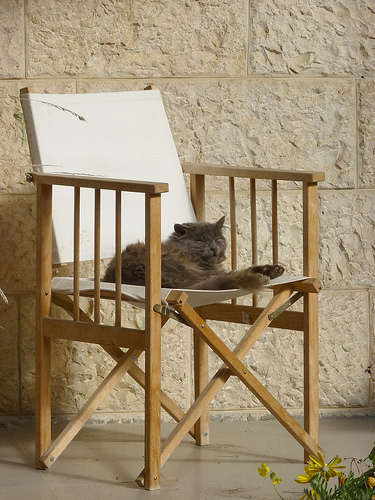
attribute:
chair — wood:
[14, 81, 331, 498]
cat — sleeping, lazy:
[102, 215, 281, 288]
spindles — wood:
[63, 184, 133, 330]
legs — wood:
[34, 313, 329, 484]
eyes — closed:
[190, 232, 225, 244]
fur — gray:
[123, 245, 144, 283]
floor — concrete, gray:
[13, 418, 367, 499]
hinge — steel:
[148, 307, 190, 331]